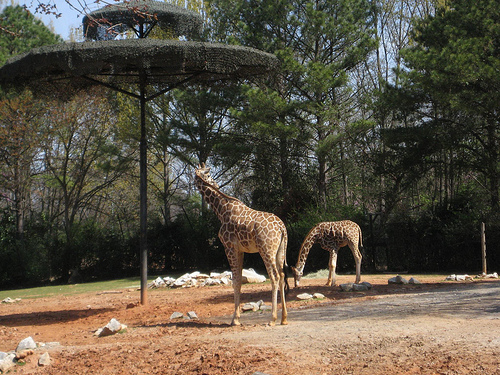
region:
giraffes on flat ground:
[62, 137, 434, 348]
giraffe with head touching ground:
[290, 207, 386, 314]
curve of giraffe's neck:
[286, 216, 331, 291]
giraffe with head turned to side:
[176, 147, 303, 327]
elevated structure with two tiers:
[10, 0, 277, 271]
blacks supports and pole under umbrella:
[56, 56, 201, 308]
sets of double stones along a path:
[165, 272, 442, 357]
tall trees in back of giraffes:
[146, 45, 442, 325]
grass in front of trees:
[16, 190, 137, 295]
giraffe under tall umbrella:
[26, 2, 287, 319]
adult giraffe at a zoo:
[175, 153, 303, 335]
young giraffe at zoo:
[286, 208, 397, 309]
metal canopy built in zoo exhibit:
[11, 6, 295, 318]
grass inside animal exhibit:
[47, 263, 122, 300]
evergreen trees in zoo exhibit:
[398, 11, 498, 281]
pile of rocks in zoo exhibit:
[155, 261, 292, 316]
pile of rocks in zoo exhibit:
[0, 324, 81, 374]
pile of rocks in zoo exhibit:
[440, 273, 499, 295]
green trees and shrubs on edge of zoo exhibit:
[28, 111, 143, 297]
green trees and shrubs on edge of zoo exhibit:
[240, 1, 484, 290]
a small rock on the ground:
[35, 350, 52, 371]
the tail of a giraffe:
[273, 222, 300, 279]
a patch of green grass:
[1, 273, 161, 303]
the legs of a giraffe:
[226, 252, 293, 329]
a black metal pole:
[134, 81, 151, 306]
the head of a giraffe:
[289, 261, 311, 284]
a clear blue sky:
[0, 0, 453, 205]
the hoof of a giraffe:
[267, 315, 278, 330]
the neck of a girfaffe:
[193, 166, 236, 221]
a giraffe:
[289, 218, 368, 296]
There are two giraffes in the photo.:
[181, 153, 389, 326]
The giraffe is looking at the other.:
[182, 152, 240, 212]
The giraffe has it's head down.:
[282, 225, 323, 305]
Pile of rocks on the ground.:
[147, 255, 277, 285]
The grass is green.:
[34, 282, 102, 292]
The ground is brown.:
[84, 295, 156, 320]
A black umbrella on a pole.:
[49, 8, 235, 135]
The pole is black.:
[115, 84, 162, 284]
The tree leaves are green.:
[439, 28, 499, 133]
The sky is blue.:
[28, 0, 109, 54]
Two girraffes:
[153, 163, 389, 345]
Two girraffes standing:
[117, 174, 410, 329]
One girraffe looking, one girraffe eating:
[157, 171, 402, 344]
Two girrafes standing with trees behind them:
[48, 168, 407, 318]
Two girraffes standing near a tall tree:
[34, 15, 434, 327]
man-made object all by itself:
[1, 6, 276, 333]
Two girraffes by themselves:
[168, 169, 464, 336]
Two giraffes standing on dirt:
[192, 161, 402, 346]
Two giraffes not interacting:
[173, 168, 408, 330]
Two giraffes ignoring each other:
[172, 175, 367, 330]